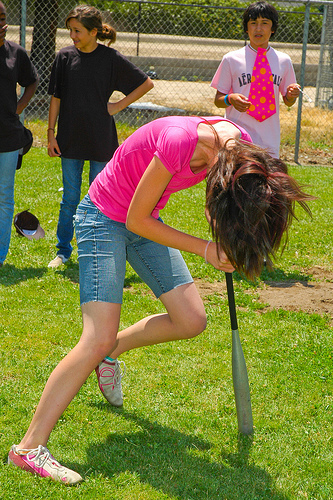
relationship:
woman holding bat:
[10, 112, 314, 486] [226, 266, 255, 434]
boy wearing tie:
[211, 1, 303, 165] [245, 48, 278, 122]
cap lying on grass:
[14, 209, 48, 243] [3, 120, 330, 499]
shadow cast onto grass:
[2, 259, 47, 295] [3, 120, 330, 499]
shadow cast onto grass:
[55, 256, 145, 290] [3, 120, 330, 499]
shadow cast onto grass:
[229, 254, 310, 292] [3, 120, 330, 499]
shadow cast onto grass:
[53, 398, 289, 499] [3, 120, 330, 499]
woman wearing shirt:
[40, 3, 156, 269] [48, 42, 149, 165]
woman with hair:
[10, 112, 314, 486] [200, 134, 314, 281]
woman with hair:
[40, 3, 156, 269] [64, 5, 117, 47]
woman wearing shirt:
[10, 112, 314, 486] [89, 114, 253, 226]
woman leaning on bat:
[10, 112, 314, 486] [226, 266, 255, 434]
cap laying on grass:
[14, 209, 48, 243] [3, 120, 330, 499]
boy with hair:
[211, 1, 303, 165] [243, 1, 279, 40]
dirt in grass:
[185, 265, 331, 318] [3, 120, 330, 499]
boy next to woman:
[211, 1, 303, 165] [40, 3, 156, 269]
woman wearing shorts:
[10, 112, 314, 486] [74, 192, 196, 302]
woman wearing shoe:
[10, 112, 314, 486] [5, 440, 85, 487]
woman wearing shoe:
[10, 112, 314, 486] [94, 352, 124, 411]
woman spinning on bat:
[10, 112, 314, 486] [226, 266, 255, 434]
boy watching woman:
[211, 1, 303, 165] [10, 112, 314, 486]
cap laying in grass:
[14, 209, 48, 243] [3, 120, 330, 499]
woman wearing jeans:
[40, 3, 156, 269] [54, 151, 110, 262]